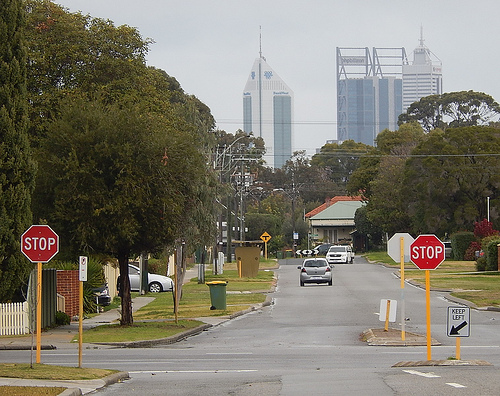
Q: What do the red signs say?
A: STOP.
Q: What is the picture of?
A: A street in a city.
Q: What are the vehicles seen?
A: Few white cars.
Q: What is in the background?
A: Tall skyscraper buildings.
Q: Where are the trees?
A: On both sides of the road.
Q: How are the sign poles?
A: Yellow colored metal poles.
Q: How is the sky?
A: Grey blue.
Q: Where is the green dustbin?
A: On the grass of the sidewalk.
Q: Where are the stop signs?
A: At the crossing.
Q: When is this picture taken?
A: During daytime.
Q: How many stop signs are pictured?
A: Two.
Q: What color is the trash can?
A: Green.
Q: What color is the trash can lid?
A: Yellow.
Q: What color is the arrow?
A: Black.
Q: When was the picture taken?
A: Daytime.